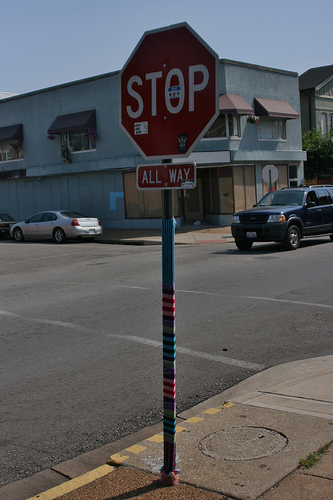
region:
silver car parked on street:
[12, 206, 114, 246]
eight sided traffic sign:
[105, 23, 224, 164]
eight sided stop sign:
[106, 19, 229, 167]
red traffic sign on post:
[107, 19, 245, 211]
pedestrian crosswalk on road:
[3, 268, 330, 380]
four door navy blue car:
[223, 166, 331, 265]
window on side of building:
[46, 110, 110, 165]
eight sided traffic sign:
[259, 163, 282, 190]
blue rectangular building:
[3, 56, 310, 234]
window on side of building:
[251, 96, 300, 146]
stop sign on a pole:
[92, 10, 253, 498]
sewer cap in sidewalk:
[194, 415, 292, 474]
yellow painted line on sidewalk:
[18, 458, 130, 494]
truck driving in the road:
[225, 174, 331, 255]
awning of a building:
[252, 92, 303, 126]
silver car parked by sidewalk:
[7, 208, 114, 252]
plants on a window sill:
[48, 140, 74, 163]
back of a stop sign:
[258, 161, 286, 193]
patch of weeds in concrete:
[298, 446, 327, 473]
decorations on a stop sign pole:
[156, 279, 185, 457]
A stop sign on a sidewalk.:
[119, 20, 220, 161]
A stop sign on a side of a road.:
[120, 19, 217, 485]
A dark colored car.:
[231, 182, 331, 252]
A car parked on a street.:
[7, 207, 102, 244]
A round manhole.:
[195, 425, 288, 461]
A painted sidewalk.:
[22, 400, 234, 498]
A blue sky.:
[0, 1, 332, 100]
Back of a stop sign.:
[259, 161, 280, 183]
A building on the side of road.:
[0, 59, 304, 227]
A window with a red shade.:
[250, 95, 298, 139]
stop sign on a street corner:
[116, 19, 219, 160]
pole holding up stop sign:
[160, 190, 176, 483]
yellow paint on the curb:
[28, 397, 238, 499]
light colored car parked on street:
[8, 207, 103, 242]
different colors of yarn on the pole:
[160, 216, 178, 481]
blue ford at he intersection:
[228, 182, 331, 249]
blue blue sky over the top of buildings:
[0, 1, 329, 99]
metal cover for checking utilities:
[197, 423, 289, 462]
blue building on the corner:
[0, 56, 305, 227]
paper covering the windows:
[122, 164, 289, 220]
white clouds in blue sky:
[210, 10, 235, 43]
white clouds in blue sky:
[9, 9, 54, 52]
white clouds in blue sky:
[14, 41, 62, 66]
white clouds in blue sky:
[59, 16, 103, 51]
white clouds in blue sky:
[272, 13, 314, 68]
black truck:
[247, 175, 329, 229]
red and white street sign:
[131, 19, 213, 153]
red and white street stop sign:
[114, 12, 226, 159]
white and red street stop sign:
[105, 21, 217, 153]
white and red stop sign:
[118, 22, 221, 151]